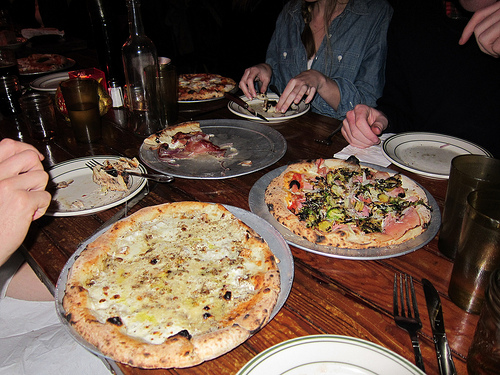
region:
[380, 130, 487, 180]
empty plate on table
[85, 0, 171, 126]
Two empty wine bottles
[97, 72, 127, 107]
salt shaker next to wine bottles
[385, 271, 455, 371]
knife and fork on table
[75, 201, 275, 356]
cheese pizza on platter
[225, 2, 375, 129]
female eating pizza with fingers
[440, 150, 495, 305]
half full beverage glasses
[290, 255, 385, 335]
wooden table in restaurant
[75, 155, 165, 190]
dirty fork on plate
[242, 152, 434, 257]
pizza on right of table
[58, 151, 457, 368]
Pizzas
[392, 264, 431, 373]
A silver fork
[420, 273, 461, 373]
A silver butter knife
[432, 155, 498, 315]
Brown colored plastic cups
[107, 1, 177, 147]
A clear bottle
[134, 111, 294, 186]
A silver pizza pan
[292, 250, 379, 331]
A wooden table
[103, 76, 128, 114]
A salt shaker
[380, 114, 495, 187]
A white plate with a dark color rim.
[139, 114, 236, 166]
A slice of pizza on a pan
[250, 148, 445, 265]
Delicious pizza with meat and vegetables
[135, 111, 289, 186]
Slice of pizza on plate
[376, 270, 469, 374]
Knife and fork on table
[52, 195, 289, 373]
Delicious pizza with cheese only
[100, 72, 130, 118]
Saltshaker on dining table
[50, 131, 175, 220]
Fork on dinner plate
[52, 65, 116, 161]
Glass of water on table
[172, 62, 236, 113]
Delicious ham and sausage pizza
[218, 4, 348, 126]
Woman having her dinner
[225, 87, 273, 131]
Sharp knife on dinner plate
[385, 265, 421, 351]
silver fork on table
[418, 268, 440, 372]
silver knife on table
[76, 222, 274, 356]
pan of pizza on table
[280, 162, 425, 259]
pan of pizza on table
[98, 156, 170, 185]
fork on white plate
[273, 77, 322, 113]
left hand of person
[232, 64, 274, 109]
right hand of person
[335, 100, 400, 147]
right hand of person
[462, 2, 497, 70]
left hand of person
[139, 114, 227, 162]
slice of pizza on pan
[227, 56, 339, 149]
Woman eating with her hands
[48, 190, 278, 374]
Cheese pizza with thick crust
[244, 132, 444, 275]
Supreme thin crust pizza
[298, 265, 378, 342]
Distressed wooden table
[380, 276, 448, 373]
Silver fork and knife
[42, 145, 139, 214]
Plate with cheese and fork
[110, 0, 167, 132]
Empty bottle of wine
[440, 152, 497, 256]
Two cups that are empty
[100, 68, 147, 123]
Salt and pepper on the table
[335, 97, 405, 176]
Mans hand sitting on table